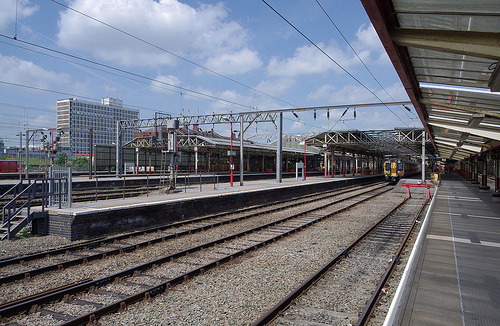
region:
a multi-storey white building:
[52, 86, 142, 152]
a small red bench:
[402, 180, 438, 198]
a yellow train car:
[381, 155, 422, 180]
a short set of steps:
[0, 207, 47, 241]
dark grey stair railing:
[1, 177, 56, 229]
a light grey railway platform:
[43, 165, 335, 238]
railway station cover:
[119, 129, 276, 150]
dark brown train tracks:
[1, 194, 396, 324]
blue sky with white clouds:
[1, 0, 361, 92]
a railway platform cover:
[364, 0, 499, 168]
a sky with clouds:
[4, 7, 430, 154]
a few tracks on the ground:
[11, 159, 410, 323]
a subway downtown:
[10, 9, 484, 323]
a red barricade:
[382, 168, 453, 213]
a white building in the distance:
[46, 83, 161, 160]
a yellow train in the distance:
[377, 143, 419, 193]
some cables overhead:
[0, 0, 428, 138]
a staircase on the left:
[0, 156, 56, 258]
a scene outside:
[4, 3, 495, 295]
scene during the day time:
[10, 17, 499, 295]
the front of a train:
[380, 150, 410, 186]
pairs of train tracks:
[0, 177, 432, 324]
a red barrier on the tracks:
[396, 176, 443, 204]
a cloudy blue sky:
[1, 0, 428, 162]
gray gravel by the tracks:
[97, 184, 402, 321]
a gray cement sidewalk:
[378, 170, 499, 323]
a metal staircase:
[0, 161, 80, 238]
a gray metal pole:
[268, 109, 288, 182]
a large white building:
[53, 93, 149, 153]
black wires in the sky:
[262, 0, 419, 130]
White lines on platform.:
[444, 212, 494, 308]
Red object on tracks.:
[393, 172, 448, 219]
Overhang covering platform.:
[371, 30, 473, 205]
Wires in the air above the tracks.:
[46, 47, 356, 94]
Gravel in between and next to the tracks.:
[193, 280, 267, 324]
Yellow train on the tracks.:
[377, 157, 438, 217]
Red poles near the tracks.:
[212, 132, 267, 236]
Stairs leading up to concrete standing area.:
[10, 180, 97, 270]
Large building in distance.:
[29, 98, 179, 190]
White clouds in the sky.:
[118, 19, 343, 66]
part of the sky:
[253, 0, 290, 57]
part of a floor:
[426, 245, 469, 310]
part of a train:
[318, 238, 355, 291]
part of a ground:
[218, 275, 243, 308]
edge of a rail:
[333, 226, 352, 261]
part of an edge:
[146, 189, 165, 203]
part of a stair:
[0, 185, 39, 222]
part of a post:
[218, 115, 253, 163]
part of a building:
[56, 113, 96, 153]